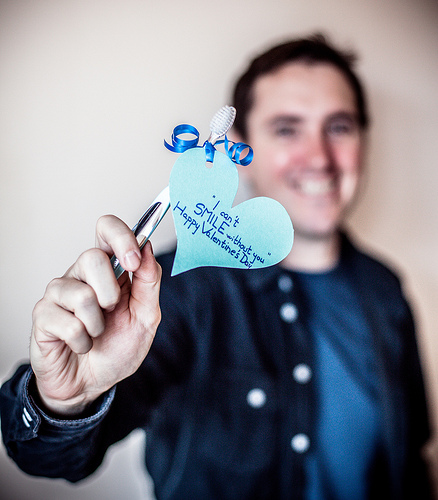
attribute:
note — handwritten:
[172, 194, 271, 268]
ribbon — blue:
[162, 123, 251, 166]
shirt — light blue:
[274, 263, 387, 498]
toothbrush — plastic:
[106, 125, 310, 301]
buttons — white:
[19, 405, 34, 427]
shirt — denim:
[3, 224, 436, 497]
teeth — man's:
[296, 176, 336, 192]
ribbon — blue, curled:
[148, 123, 281, 178]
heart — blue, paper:
[166, 120, 306, 292]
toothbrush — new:
[112, 105, 239, 279]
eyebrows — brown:
[266, 108, 363, 124]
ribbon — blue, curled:
[160, 121, 257, 171]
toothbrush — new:
[101, 103, 243, 290]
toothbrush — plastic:
[26, 82, 261, 420]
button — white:
[275, 273, 296, 290]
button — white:
[280, 299, 298, 322]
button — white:
[292, 361, 312, 383]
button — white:
[290, 431, 310, 452]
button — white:
[246, 385, 268, 408]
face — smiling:
[254, 62, 365, 233]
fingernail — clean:
[121, 248, 142, 271]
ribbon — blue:
[165, 121, 251, 162]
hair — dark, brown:
[227, 34, 369, 138]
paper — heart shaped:
[169, 145, 297, 283]